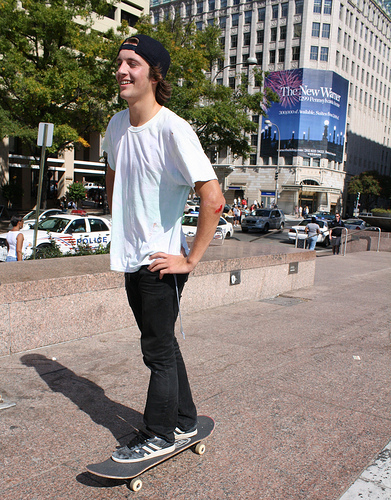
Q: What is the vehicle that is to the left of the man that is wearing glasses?
A: The vehicle is a SUV.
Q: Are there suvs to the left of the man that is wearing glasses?
A: Yes, there is a SUV to the left of the man.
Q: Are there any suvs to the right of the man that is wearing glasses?
A: No, the SUV is to the left of the man.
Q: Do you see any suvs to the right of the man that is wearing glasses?
A: No, the SUV is to the left of the man.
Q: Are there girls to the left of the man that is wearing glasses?
A: No, there is a SUV to the left of the man.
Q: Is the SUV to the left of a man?
A: Yes, the SUV is to the left of a man.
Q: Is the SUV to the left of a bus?
A: No, the SUV is to the left of a man.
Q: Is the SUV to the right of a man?
A: No, the SUV is to the left of a man.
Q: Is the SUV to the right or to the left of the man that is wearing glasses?
A: The SUV is to the left of the man.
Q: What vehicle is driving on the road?
A: The vehicle is a SUV.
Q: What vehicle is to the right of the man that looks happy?
A: The vehicle is a SUV.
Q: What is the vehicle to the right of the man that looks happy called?
A: The vehicle is a SUV.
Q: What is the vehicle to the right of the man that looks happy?
A: The vehicle is a SUV.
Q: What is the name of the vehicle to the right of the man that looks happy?
A: The vehicle is a SUV.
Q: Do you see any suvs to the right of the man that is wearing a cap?
A: Yes, there is a SUV to the right of the man.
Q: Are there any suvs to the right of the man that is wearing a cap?
A: Yes, there is a SUV to the right of the man.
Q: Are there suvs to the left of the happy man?
A: No, the SUV is to the right of the man.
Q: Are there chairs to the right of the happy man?
A: No, there is a SUV to the right of the man.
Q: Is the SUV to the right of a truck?
A: No, the SUV is to the right of a man.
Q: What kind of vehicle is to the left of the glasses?
A: The vehicle is a SUV.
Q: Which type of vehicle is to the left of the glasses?
A: The vehicle is a SUV.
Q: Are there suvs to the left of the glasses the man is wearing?
A: Yes, there is a SUV to the left of the glasses.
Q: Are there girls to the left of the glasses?
A: No, there is a SUV to the left of the glasses.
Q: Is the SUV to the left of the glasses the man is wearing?
A: Yes, the SUV is to the left of the glasses.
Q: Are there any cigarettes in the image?
A: No, there are no cigarettes.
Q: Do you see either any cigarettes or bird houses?
A: No, there are no cigarettes or bird houses.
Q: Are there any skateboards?
A: Yes, there is a skateboard.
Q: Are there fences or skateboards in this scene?
A: Yes, there is a skateboard.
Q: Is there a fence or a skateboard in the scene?
A: Yes, there is a skateboard.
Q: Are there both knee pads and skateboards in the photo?
A: No, there is a skateboard but no knee pads.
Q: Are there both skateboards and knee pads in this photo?
A: No, there is a skateboard but no knee pads.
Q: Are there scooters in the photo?
A: No, there are no scooters.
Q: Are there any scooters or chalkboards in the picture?
A: No, there are no scooters or chalkboards.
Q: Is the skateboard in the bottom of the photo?
A: Yes, the skateboard is in the bottom of the image.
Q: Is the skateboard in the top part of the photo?
A: No, the skateboard is in the bottom of the image.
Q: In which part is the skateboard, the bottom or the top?
A: The skateboard is in the bottom of the image.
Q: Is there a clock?
A: No, there are no clocks.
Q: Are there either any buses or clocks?
A: No, there are no clocks or buses.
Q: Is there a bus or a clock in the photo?
A: No, there are no clocks or buses.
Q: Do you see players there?
A: No, there are no players.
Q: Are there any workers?
A: No, there are no workers.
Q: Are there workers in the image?
A: No, there are no workers.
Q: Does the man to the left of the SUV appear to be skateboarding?
A: Yes, the man is skateboarding.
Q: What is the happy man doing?
A: The man is skateboarding.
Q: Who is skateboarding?
A: The man is skateboarding.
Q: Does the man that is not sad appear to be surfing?
A: No, the man is skateboarding.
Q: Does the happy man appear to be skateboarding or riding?
A: The man is skateboarding.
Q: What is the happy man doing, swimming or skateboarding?
A: The man is skateboarding.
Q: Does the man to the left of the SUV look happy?
A: Yes, the man is happy.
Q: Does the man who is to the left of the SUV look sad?
A: No, the man is happy.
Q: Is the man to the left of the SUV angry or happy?
A: The man is happy.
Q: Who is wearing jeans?
A: The man is wearing jeans.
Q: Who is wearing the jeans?
A: The man is wearing jeans.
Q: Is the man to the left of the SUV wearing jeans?
A: Yes, the man is wearing jeans.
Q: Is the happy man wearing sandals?
A: No, the man is wearing jeans.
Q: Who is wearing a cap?
A: The man is wearing a cap.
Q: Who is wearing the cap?
A: The man is wearing a cap.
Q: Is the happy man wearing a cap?
A: Yes, the man is wearing a cap.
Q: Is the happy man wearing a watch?
A: No, the man is wearing a cap.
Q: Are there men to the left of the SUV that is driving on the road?
A: Yes, there is a man to the left of the SUV.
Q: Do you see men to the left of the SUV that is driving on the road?
A: Yes, there is a man to the left of the SUV.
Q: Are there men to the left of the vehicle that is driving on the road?
A: Yes, there is a man to the left of the SUV.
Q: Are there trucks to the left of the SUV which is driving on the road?
A: No, there is a man to the left of the SUV.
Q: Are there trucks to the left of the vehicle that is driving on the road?
A: No, there is a man to the left of the SUV.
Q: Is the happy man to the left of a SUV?
A: Yes, the man is to the left of a SUV.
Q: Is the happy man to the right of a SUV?
A: No, the man is to the left of a SUV.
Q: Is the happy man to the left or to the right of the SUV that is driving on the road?
A: The man is to the left of the SUV.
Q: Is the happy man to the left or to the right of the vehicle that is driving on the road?
A: The man is to the left of the SUV.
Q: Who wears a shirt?
A: The man wears a shirt.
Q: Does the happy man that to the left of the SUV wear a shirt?
A: Yes, the man wears a shirt.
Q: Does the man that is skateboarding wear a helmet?
A: No, the man wears a shirt.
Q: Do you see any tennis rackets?
A: No, there are no tennis rackets.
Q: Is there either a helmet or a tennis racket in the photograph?
A: No, there are no rackets or helmets.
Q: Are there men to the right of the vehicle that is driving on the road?
A: Yes, there is a man to the right of the SUV.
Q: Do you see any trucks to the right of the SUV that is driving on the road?
A: No, there is a man to the right of the SUV.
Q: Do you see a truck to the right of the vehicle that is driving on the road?
A: No, there is a man to the right of the SUV.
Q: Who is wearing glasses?
A: The man is wearing glasses.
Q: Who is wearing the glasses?
A: The man is wearing glasses.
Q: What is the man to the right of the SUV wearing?
A: The man is wearing glasses.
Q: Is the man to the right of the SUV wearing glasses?
A: Yes, the man is wearing glasses.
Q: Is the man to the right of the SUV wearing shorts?
A: No, the man is wearing glasses.